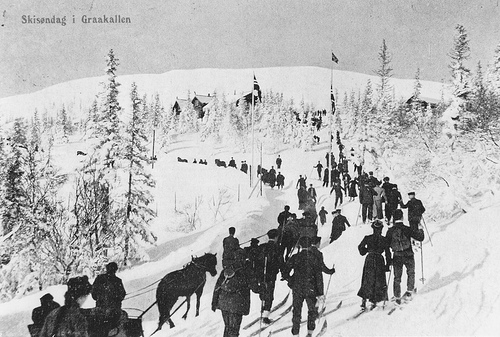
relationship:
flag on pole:
[253, 75, 263, 102] [252, 93, 254, 202]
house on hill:
[192, 95, 219, 122] [0, 65, 498, 154]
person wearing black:
[287, 236, 328, 336] [285, 250, 325, 298]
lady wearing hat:
[359, 220, 391, 314] [373, 219, 385, 230]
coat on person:
[213, 267, 267, 310] [212, 249, 266, 336]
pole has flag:
[252, 93, 254, 202] [253, 75, 263, 102]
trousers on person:
[291, 285, 317, 331] [287, 236, 328, 336]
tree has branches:
[111, 82, 159, 268] [129, 168, 152, 178]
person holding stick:
[287, 236, 328, 336] [320, 263, 336, 319]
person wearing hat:
[287, 236, 328, 336] [299, 236, 312, 248]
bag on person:
[222, 268, 238, 293] [212, 249, 266, 336]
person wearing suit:
[403, 191, 426, 228] [401, 198, 426, 229]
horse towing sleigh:
[156, 252, 216, 327] [77, 297, 146, 336]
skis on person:
[281, 321, 332, 337] [287, 236, 328, 336]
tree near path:
[111, 82, 159, 268] [141, 187, 290, 300]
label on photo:
[22, 13, 131, 24] [1, 2, 499, 335]